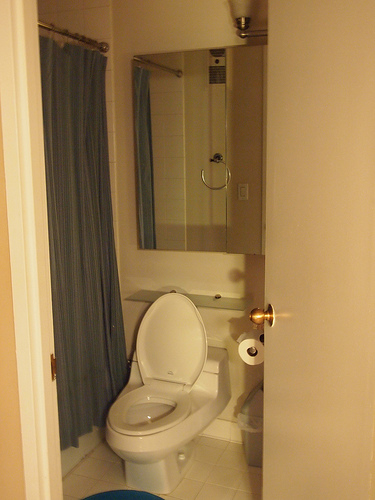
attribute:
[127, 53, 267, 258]
mirror — clear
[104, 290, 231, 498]
toilet — white, open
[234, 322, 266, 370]
toilet paper — white, roll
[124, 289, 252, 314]
shelf — glass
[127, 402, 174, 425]
toilet bowl — white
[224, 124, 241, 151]
ground — white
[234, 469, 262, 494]
tile — small, white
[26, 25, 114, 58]
rod — shower curtain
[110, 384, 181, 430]
seat — white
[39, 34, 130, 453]
shower curtain — brown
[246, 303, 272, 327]
doorknob — brass color, round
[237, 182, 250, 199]
light switch — white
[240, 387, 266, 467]
trash can — grey, small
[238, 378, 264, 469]
garbage can — metal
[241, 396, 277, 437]
trashbag — clear, plastic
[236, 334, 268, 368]
toilet paper — white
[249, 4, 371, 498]
door — brown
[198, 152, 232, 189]
ring — silver, towel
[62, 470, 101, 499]
tile — white, small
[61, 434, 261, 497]
floor — white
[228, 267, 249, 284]
shadow — reflection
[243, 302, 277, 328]
doorknob — brass color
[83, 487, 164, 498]
bath mat — blue